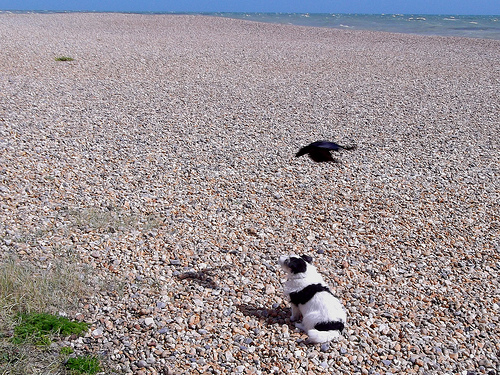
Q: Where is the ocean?
A: Next to the gravel.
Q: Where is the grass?
A: To the left.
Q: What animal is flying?
A: Bird.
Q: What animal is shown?
A: A dog.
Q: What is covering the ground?
A: Pebbles.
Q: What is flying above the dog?
A: A bird.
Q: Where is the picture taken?
A: A beach.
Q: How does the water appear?
A: Blue.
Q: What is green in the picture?
A: Grass.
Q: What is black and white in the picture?
A: A dog.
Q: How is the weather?
A: Sunny and clear.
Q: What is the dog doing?
A: Sitting.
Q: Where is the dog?
A: On the rocks.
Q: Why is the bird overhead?
A: Flying.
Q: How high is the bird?
A: Very low.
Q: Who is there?
A: No one.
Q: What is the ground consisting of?
A: Rocks.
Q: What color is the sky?
A: Blue.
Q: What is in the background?
A: Ocean.